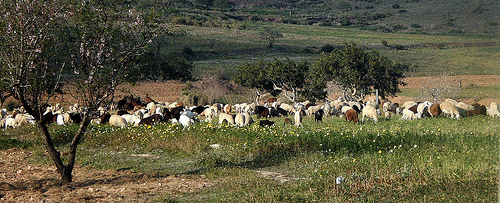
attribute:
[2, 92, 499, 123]
sheep — herded, tan, white, brown, multi colored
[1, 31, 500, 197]
field — grassy, dirt, green, brown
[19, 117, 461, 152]
flowers — white, yellow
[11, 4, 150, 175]
tree — forked, tall, skinny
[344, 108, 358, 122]
sheep — brown, tan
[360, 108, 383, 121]
sheep — white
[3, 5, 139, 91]
flowers — purple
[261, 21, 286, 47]
tree — small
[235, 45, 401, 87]
tops — green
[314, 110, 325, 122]
sheep — black